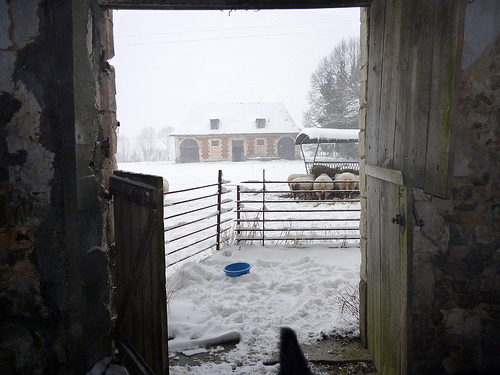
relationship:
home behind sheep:
[171, 101, 312, 179] [271, 152, 369, 203]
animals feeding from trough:
[287, 166, 361, 204] [293, 127, 361, 175]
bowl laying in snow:
[223, 262, 254, 278] [167, 243, 357, 330]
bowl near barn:
[223, 262, 254, 278] [5, 7, 492, 371]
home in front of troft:
[171, 101, 312, 179] [294, 124, 358, 176]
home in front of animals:
[171, 101, 312, 179] [281, 161, 358, 201]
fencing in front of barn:
[163, 164, 358, 267] [5, 7, 492, 371]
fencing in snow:
[163, 164, 358, 267] [164, 241, 361, 354]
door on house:
[206, 134, 227, 159] [164, 102, 309, 163]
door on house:
[254, 137, 270, 156] [164, 102, 309, 163]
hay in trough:
[305, 159, 365, 178] [291, 123, 364, 172]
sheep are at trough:
[283, 163, 364, 202] [291, 123, 364, 172]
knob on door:
[391, 210, 407, 228] [352, 162, 417, 370]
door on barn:
[352, 162, 417, 370] [5, 7, 492, 371]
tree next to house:
[311, 56, 364, 135] [168, 105, 301, 165]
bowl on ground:
[223, 262, 254, 278] [164, 240, 362, 338]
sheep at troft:
[285, 169, 308, 184] [291, 125, 362, 175]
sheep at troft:
[292, 175, 317, 202] [291, 125, 362, 175]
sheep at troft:
[311, 173, 335, 197] [291, 125, 362, 175]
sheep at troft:
[335, 175, 356, 196] [291, 125, 362, 175]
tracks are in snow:
[263, 257, 336, 307] [167, 243, 357, 330]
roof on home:
[167, 108, 299, 137] [171, 101, 312, 179]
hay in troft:
[305, 159, 365, 178] [294, 124, 358, 176]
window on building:
[252, 137, 267, 146] [168, 104, 301, 159]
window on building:
[229, 138, 247, 148] [170, 101, 296, 162]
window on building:
[207, 115, 225, 132] [165, 95, 302, 161]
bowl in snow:
[219, 245, 273, 273] [181, 245, 350, 325]